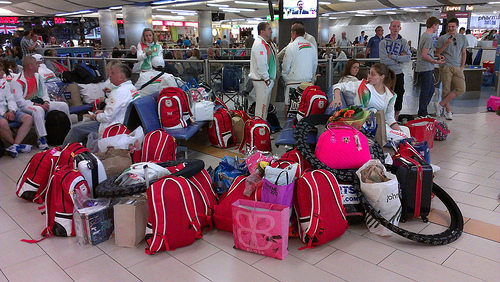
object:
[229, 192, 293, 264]
gift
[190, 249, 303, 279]
ground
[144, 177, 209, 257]
backpack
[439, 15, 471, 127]
person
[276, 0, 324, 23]
tv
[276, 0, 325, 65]
wall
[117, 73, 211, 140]
chair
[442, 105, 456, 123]
shoe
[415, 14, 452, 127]
people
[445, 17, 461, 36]
head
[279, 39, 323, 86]
jacket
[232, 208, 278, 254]
butterfly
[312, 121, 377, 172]
bag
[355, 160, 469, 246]
wheel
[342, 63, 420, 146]
woman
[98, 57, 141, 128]
man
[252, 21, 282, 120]
men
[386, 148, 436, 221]
suitcase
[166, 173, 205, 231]
trim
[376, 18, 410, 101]
boy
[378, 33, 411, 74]
sweatshirt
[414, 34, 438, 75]
tee shirts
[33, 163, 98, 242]
backpacks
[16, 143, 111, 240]
group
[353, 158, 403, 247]
bag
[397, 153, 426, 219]
stripe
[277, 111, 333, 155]
bench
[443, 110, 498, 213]
floor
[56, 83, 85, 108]
sack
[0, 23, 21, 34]
flag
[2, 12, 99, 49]
wall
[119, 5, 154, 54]
pillar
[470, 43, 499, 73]
counter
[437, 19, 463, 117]
passengers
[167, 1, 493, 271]
airport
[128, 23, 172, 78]
passenger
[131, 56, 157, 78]
bag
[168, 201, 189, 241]
red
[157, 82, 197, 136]
carry on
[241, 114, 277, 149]
carry on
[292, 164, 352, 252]
backpack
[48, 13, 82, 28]
sign